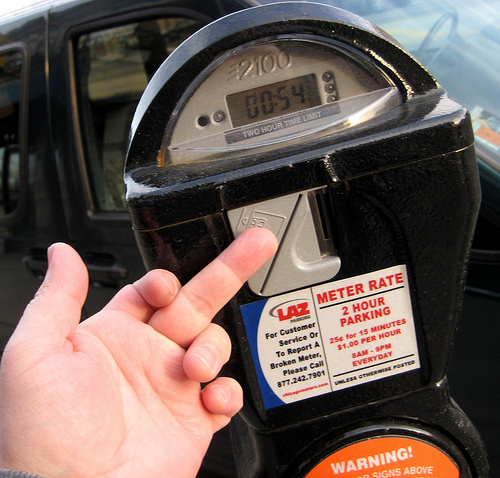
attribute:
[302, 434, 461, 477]
sticker — orange, warning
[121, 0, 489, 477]
meter — black, metallic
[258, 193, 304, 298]
coin slot — grey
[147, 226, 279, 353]
middle finger — extended, pointing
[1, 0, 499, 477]
vehicle — black, parked, behind, dark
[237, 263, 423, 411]
sticker — red white, blue, white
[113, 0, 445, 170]
top — rounded, black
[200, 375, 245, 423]
pinkie — bent